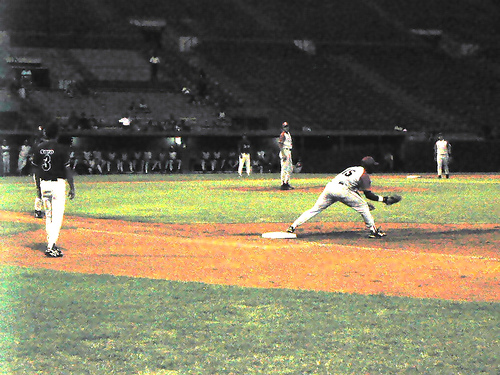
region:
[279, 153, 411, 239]
person on baseball field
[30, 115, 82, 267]
person on baseball field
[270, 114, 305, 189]
person on baseball field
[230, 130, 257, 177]
person on baseball field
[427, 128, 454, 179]
person on baseball field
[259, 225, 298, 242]
base on baseball field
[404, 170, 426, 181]
base on baseball field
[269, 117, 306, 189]
person in a uniform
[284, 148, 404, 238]
person in a uniform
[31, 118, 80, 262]
person in a uniform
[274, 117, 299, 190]
Player on pitcher's mound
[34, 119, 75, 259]
Baseline coach with white pants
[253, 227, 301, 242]
Base for baseball game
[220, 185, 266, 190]
dirt part of pitcher's mound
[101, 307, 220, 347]
Green grassy part of ballfield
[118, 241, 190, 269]
Dirt part of baseline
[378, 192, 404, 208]
Ball player's leather glove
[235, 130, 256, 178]
Sideline coach with white pants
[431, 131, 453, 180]
Baseball Player watching throw in progress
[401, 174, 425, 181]
Base for baseball game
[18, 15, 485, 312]
baseball game on grass and dirt field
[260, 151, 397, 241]
player with foot on base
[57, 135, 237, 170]
players seated in a row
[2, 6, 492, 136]
a few spectators in empty stadium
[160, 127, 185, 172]
light shining above player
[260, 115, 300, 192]
pitcher standing tall on mound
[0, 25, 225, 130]
seating divided into squares and rectangle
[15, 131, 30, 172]
player leaning against wall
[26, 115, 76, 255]
player with arms at sides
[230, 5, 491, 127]
stadium seating in low light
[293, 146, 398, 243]
player leaning to catch ball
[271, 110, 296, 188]
pitcher looking at first baseman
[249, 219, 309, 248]
base is on the ground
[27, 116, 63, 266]
player wearing number 3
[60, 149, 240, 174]
players on the bench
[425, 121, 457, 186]
player on third base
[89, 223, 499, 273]
baseline is marked in white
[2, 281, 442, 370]
grass surrounds the baseline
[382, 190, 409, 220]
player has black mitt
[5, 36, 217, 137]
spectators in the stands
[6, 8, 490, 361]
Photo taken during a baseball game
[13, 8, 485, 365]
Photo taken at a baseball stadium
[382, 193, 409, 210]
Glove on the right hand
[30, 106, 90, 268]
#3 on the first base line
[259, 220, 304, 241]
First base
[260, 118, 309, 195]
Pitcher on the mound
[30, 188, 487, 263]
White line on the field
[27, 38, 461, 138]
Few people in the stands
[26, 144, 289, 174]
Opposing team on the bench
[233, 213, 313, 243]
The base is white